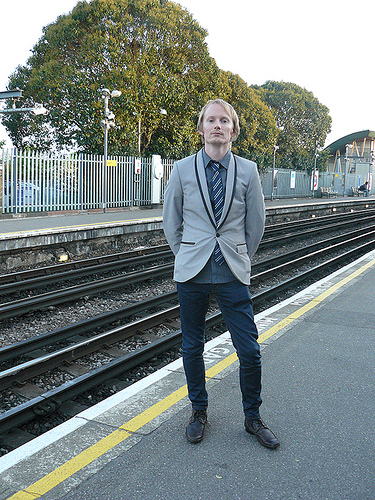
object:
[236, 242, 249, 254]
pocket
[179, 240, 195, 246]
pocket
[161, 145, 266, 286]
jacket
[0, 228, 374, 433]
train tracks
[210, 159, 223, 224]
tie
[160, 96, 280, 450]
man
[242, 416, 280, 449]
foot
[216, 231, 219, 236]
button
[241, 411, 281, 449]
shoe